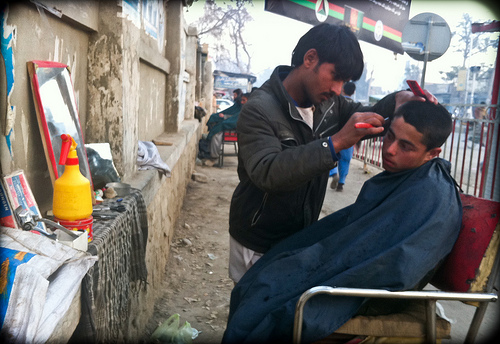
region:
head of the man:
[263, 12, 378, 105]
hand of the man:
[327, 98, 388, 159]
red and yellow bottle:
[31, 113, 123, 230]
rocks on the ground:
[151, 218, 221, 305]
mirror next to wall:
[13, 43, 113, 173]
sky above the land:
[227, 6, 291, 57]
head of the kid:
[338, 83, 464, 202]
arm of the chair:
[278, 261, 473, 330]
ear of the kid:
[406, 133, 457, 184]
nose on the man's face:
[326, 76, 350, 103]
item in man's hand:
[328, 100, 390, 153]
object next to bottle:
[11, 47, 108, 128]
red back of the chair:
[443, 193, 496, 263]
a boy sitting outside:
[362, 95, 469, 332]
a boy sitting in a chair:
[360, 81, 495, 326]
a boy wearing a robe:
[244, 128, 489, 280]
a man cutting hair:
[205, 27, 451, 334]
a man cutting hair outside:
[219, 30, 482, 333]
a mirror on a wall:
[18, 41, 140, 241]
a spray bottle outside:
[26, 113, 178, 302]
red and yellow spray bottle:
[34, 120, 149, 270]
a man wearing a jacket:
[202, 20, 361, 321]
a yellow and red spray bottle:
[48, 131, 94, 243]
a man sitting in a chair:
[295, 95, 490, 340]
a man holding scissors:
[345, 99, 398, 141]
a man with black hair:
[296, 20, 369, 71]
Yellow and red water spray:
[51, 132, 94, 221]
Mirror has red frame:
[26, 58, 98, 208]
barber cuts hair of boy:
[229, 22, 434, 287]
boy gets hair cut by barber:
[217, 100, 462, 342]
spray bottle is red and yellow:
[49, 131, 94, 238]